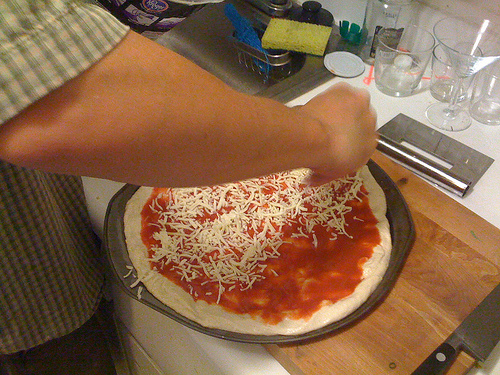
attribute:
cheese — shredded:
[208, 279, 223, 304]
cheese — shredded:
[129, 271, 144, 292]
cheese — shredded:
[337, 220, 354, 242]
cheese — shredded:
[271, 265, 279, 280]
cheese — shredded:
[353, 190, 364, 207]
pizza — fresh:
[148, 166, 371, 313]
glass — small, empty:
[374, 21, 429, 100]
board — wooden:
[267, 150, 497, 372]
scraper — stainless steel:
[370, 107, 495, 194]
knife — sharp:
[412, 278, 499, 373]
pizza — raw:
[118, 160, 388, 329]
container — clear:
[372, 17, 436, 97]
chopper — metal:
[369, 113, 499, 198]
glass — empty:
[430, 15, 491, 128]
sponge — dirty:
[260, 16, 329, 58]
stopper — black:
[103, 0, 184, 32]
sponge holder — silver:
[241, 3, 298, 70]